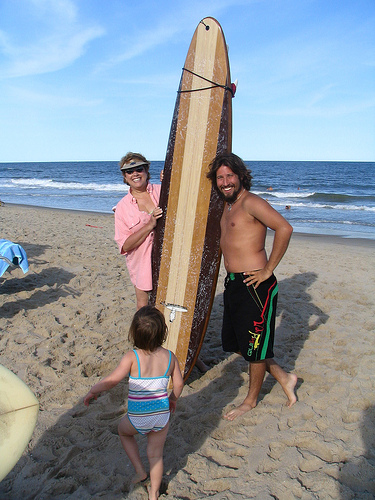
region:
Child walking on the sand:
[80, 303, 185, 499]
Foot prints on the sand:
[175, 419, 371, 499]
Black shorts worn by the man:
[222, 270, 276, 360]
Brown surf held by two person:
[150, 15, 234, 391]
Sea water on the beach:
[2, 162, 374, 240]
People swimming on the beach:
[261, 185, 301, 210]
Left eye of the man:
[227, 173, 235, 177]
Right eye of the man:
[215, 174, 223, 179]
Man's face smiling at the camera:
[212, 164, 243, 199]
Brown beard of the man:
[222, 192, 238, 203]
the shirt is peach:
[100, 188, 180, 289]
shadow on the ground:
[201, 267, 338, 425]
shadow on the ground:
[221, 283, 319, 381]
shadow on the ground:
[266, 293, 327, 404]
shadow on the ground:
[273, 255, 342, 393]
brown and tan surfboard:
[149, 16, 232, 381]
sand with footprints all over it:
[0, 202, 373, 498]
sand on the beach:
[0, 200, 373, 498]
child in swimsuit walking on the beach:
[84, 306, 184, 498]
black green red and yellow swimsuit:
[221, 271, 279, 361]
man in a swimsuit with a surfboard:
[206, 154, 298, 422]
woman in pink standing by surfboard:
[113, 151, 164, 309]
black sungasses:
[124, 166, 143, 173]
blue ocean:
[0, 159, 373, 237]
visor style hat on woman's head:
[120, 161, 147, 169]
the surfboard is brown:
[151, 10, 230, 365]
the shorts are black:
[207, 250, 307, 408]